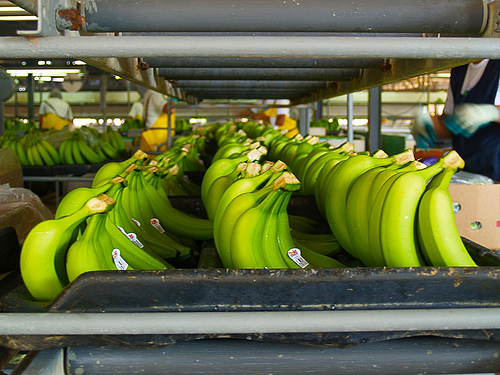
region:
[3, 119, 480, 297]
bananas being processed on the assembly line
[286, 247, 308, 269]
merchant's sticker on a green banana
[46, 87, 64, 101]
a worker's hairnet for sanitation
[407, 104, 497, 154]
blue and white gloves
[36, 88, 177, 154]
worker's on an assembly line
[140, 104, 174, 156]
a yellow apron for worker's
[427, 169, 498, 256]
a cardboard shipping box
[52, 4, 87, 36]
a rusty piece of equipment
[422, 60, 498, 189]
a worker's blue and white uniform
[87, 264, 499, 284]
rusty scratches on a metal bar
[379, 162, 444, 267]
a yellow green banana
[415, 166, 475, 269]
a yellow green banana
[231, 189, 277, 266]
a yellow green banana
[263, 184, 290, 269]
a yellow green banana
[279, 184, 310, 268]
a yellow green banana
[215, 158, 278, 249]
a yellow green banana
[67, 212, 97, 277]
a yellow green banana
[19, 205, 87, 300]
a yellow green banana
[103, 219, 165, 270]
a yellow green banana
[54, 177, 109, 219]
a yellow green banana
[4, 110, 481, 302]
bananas sitting in rows in factory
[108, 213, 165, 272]
white labels on bananas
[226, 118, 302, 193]
tops of bananas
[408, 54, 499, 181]
part of upper body of person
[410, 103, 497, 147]
white and blue gloves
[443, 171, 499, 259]
part of cardboard box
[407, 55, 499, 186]
part of person wearing blue vest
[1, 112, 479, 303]
many bunches of green bananas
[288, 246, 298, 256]
red emblem on white sticker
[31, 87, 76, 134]
upper body of person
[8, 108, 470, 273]
many rows of bananas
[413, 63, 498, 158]
person standing beside bananas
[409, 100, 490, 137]
white gloves with blue fingertips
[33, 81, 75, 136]
person wearing white shirt in background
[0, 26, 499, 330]
two white bars running horizontally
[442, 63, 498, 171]
navy blue vest of person standing beside bananas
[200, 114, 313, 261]
middle row of bananas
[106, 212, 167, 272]
sticks on banana bunches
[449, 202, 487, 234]
two silver bolts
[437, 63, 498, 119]
white shirt of person standing beside bananas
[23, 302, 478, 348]
The metal pole is gray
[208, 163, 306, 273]
The bunch of bananas are green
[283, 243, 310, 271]
The sticker on the bananas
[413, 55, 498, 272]
A person stocking the shelf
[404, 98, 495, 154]
The person has on gloves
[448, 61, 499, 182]
The person has on a blue vest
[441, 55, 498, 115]
The person has a white shirt on under the vest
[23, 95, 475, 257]
A large group of bananas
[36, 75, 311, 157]
A group of worker's in the building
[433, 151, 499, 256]
A cardboard box on a cart